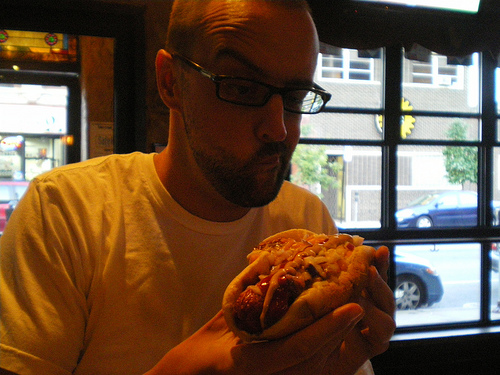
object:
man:
[0, 0, 397, 375]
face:
[175, 11, 321, 209]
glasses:
[170, 52, 331, 116]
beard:
[197, 143, 293, 208]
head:
[156, 0, 321, 213]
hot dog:
[221, 227, 389, 347]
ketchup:
[259, 271, 290, 296]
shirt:
[0, 151, 374, 374]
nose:
[256, 100, 291, 144]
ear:
[155, 49, 180, 116]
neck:
[150, 111, 249, 245]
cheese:
[267, 232, 341, 299]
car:
[394, 190, 499, 230]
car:
[391, 254, 443, 309]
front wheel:
[392, 271, 424, 312]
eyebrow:
[217, 46, 263, 80]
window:
[1, 28, 80, 77]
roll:
[217, 251, 282, 348]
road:
[396, 241, 500, 310]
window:
[393, 144, 489, 243]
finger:
[275, 302, 365, 365]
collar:
[146, 152, 260, 236]